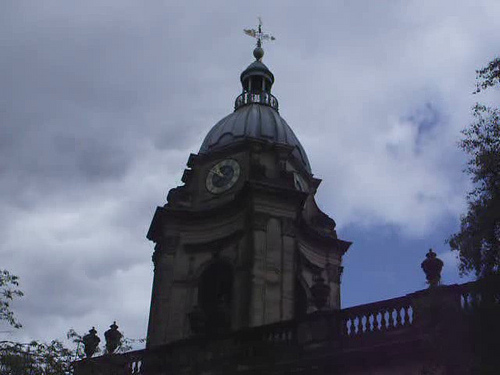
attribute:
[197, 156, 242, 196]
clock — roman numeral, in the building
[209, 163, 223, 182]
two needles — in the clock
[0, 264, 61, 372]
leaves/branches — of the tree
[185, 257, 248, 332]
design — in the building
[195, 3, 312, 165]
top — of the building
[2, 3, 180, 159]
skies — with clouds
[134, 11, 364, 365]
old building — big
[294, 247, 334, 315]
design — of the building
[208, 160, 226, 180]
two needle — in the roman letter clock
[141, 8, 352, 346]
tower — on an old building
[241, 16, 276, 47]
turret — on the tower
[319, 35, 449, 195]
clouds — in the sky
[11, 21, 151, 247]
clouds — in the sky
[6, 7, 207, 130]
blue sky — next to tower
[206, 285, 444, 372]
decorative holes — in the top of a wall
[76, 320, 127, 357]
two decorations — on the top of a wall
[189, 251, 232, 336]
bell chamber — in a steeple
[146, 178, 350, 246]
fancy woodwork — around a steeple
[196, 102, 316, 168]
dome top — roof portion of a steeple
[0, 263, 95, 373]
tree — old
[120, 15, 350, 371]
church building — dark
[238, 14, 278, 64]
weather vane — at the top of a church steeple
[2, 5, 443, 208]
cloudy sky — mostly dark, with some blue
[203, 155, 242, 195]
clock — on a building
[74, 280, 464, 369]
cement railing — in front of building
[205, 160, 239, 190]
white area — on the clock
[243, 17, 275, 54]
cross — on top of building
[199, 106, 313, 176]
dome — on the building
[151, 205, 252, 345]
section — rounded out, of building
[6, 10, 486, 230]
clouds — white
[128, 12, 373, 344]
building — old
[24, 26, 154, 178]
clouds — gray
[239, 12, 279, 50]
weather vein — pointing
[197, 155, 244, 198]
clock — round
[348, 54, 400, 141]
clouds — white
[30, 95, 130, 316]
clouds — white, fluffy